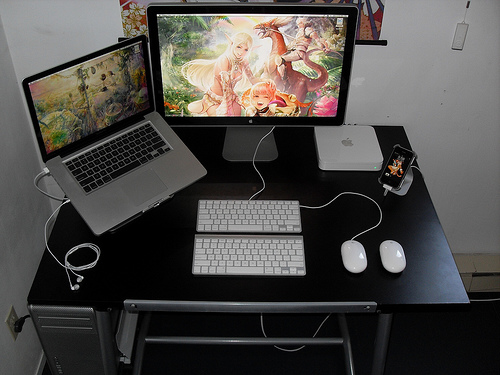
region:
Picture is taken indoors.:
[36, 26, 494, 346]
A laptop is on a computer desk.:
[17, 43, 187, 250]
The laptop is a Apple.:
[30, 61, 167, 216]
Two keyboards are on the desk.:
[191, 191, 310, 340]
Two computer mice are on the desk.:
[319, 189, 433, 304]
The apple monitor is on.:
[176, 26, 308, 144]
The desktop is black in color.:
[171, 127, 385, 284]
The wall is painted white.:
[444, 76, 496, 198]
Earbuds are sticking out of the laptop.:
[37, 197, 109, 310]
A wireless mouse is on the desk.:
[378, 231, 415, 286]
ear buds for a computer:
[62, 240, 102, 292]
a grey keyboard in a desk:
[187, 227, 309, 275]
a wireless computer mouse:
[378, 232, 424, 279]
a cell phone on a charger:
[379, 140, 423, 198]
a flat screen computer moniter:
[145, 5, 364, 131]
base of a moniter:
[216, 120, 283, 169]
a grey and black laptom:
[34, 64, 159, 196]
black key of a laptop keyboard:
[60, 124, 172, 193]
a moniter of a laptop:
[24, 49, 156, 121]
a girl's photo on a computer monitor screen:
[200, 29, 267, 84]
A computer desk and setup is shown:
[20, 9, 469, 349]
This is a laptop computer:
[22, 38, 202, 230]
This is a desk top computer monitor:
[145, 1, 361, 157]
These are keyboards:
[190, 190, 310, 280]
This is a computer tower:
[23, 225, 100, 369]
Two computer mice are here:
[334, 223, 419, 288]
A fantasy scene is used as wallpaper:
[160, 17, 342, 114]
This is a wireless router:
[311, 120, 386, 172]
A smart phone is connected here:
[380, 140, 422, 200]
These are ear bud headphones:
[39, 234, 105, 294]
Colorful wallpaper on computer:
[159, 14, 339, 118]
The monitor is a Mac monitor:
[148, 2, 349, 127]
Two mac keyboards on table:
[193, 196, 313, 281]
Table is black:
[29, 116, 499, 296]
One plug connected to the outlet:
[8, 303, 43, 345]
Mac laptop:
[3, 53, 228, 218]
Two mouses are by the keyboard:
[335, 230, 417, 281]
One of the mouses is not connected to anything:
[376, 233, 413, 278]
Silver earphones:
[35, 219, 113, 306]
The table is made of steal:
[29, 303, 109, 373]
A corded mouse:
[333, 227, 369, 274]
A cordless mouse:
[374, 233, 410, 279]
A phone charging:
[362, 128, 425, 196]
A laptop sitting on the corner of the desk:
[10, 24, 219, 240]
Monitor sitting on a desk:
[133, 2, 374, 143]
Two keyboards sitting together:
[192, 187, 316, 293]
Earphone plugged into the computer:
[42, 235, 111, 294]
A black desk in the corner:
[40, 119, 479, 322]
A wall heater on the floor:
[451, 237, 499, 307]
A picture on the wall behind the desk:
[109, 2, 394, 52]